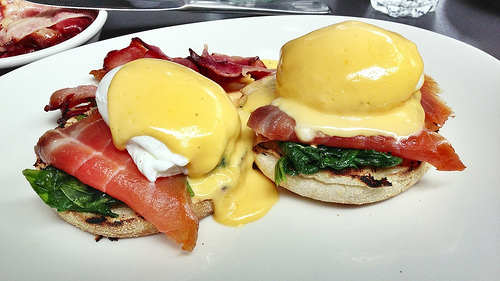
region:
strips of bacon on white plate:
[41, 39, 257, 97]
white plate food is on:
[9, 17, 494, 268]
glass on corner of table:
[364, 0, 446, 17]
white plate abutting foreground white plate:
[3, 7, 108, 71]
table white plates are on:
[5, 9, 497, 244]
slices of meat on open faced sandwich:
[45, 103, 465, 223]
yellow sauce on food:
[115, 23, 425, 223]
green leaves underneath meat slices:
[34, 139, 389, 209]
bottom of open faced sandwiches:
[34, 177, 423, 248]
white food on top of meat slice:
[87, 68, 184, 179]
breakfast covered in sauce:
[3, 20, 498, 278]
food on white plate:
[7, 16, 494, 278]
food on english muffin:
[258, 21, 455, 204]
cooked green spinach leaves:
[278, 143, 398, 172]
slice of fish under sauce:
[252, 109, 460, 171]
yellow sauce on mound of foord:
[273, 17, 426, 111]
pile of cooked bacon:
[50, 36, 267, 116]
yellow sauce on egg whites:
[93, 58, 234, 181]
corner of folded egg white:
[127, 139, 184, 182]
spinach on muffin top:
[21, 166, 146, 238]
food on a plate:
[7, 15, 497, 277]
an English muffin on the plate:
[255, 141, 463, 209]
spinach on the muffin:
[264, 136, 405, 176]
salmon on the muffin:
[240, 97, 471, 179]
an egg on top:
[266, 19, 432, 104]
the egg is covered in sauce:
[260, 16, 431, 137]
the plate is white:
[6, 16, 496, 276]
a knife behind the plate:
[20, 0, 345, 15]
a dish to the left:
[8, 3, 99, 77]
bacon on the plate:
[66, 34, 268, 108]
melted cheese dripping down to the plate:
[127, 71, 265, 207]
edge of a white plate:
[456, 34, 496, 84]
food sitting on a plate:
[230, 23, 465, 199]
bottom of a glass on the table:
[370, 0, 447, 20]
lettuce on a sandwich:
[30, 162, 107, 226]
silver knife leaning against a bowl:
[0, 0, 342, 20]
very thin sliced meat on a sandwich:
[40, 118, 195, 245]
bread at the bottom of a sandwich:
[266, 145, 424, 207]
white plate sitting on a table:
[436, 16, 496, 94]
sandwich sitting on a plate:
[254, 17, 464, 208]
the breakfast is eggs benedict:
[22, 15, 470, 252]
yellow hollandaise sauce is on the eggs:
[101, 20, 421, 225]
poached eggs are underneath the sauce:
[96, 67, 192, 179]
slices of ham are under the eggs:
[48, 92, 458, 221]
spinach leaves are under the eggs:
[35, 149, 419, 203]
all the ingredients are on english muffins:
[30, 95, 447, 233]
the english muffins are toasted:
[53, 149, 434, 231]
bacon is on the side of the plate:
[38, 36, 271, 113]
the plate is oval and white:
[3, 15, 498, 280]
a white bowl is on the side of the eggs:
[4, 3, 105, 67]